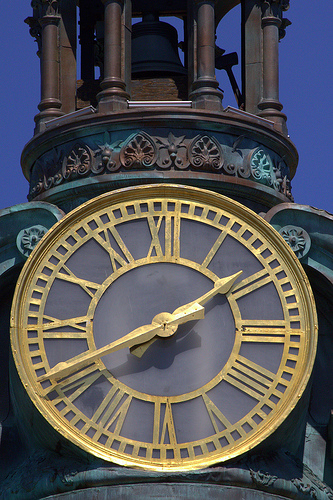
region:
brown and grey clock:
[10, 185, 317, 473]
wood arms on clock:
[42, 269, 241, 382]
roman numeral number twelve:
[146, 216, 180, 256]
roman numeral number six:
[152, 401, 175, 445]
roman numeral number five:
[201, 392, 230, 432]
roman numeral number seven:
[91, 385, 132, 435]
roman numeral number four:
[222, 355, 274, 399]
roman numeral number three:
[242, 316, 284, 345]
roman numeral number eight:
[49, 358, 99, 403]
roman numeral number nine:
[40, 314, 87, 339]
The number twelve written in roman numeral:
[141, 207, 186, 267]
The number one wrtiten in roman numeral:
[201, 227, 229, 268]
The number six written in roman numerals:
[150, 395, 178, 453]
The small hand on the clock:
[133, 270, 244, 317]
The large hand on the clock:
[29, 305, 204, 386]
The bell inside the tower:
[125, 14, 180, 85]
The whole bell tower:
[23, 2, 293, 195]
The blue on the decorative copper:
[44, 128, 289, 185]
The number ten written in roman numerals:
[55, 258, 102, 306]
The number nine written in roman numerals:
[37, 309, 95, 348]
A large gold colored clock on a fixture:
[8, 179, 323, 472]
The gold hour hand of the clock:
[168, 267, 247, 332]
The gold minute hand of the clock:
[36, 296, 205, 393]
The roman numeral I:
[200, 225, 228, 273]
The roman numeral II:
[219, 266, 274, 303]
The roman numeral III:
[233, 314, 289, 350]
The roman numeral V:
[196, 391, 236, 435]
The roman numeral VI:
[150, 395, 179, 450]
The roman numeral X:
[52, 262, 101, 303]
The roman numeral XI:
[92, 224, 136, 271]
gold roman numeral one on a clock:
[200, 230, 232, 269]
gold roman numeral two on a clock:
[225, 265, 272, 298]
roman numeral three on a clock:
[233, 319, 286, 343]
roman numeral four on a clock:
[221, 352, 275, 401]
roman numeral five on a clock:
[197, 390, 235, 431]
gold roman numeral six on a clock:
[151, 398, 180, 446]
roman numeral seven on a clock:
[90, 381, 133, 435]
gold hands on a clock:
[34, 269, 247, 383]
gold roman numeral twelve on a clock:
[144, 215, 184, 261]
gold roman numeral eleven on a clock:
[90, 225, 140, 272]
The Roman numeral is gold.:
[140, 208, 188, 263]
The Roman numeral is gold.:
[191, 223, 240, 271]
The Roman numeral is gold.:
[186, 386, 240, 440]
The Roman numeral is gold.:
[140, 390, 191, 461]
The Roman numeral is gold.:
[87, 380, 139, 440]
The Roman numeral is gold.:
[36, 307, 95, 346]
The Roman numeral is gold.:
[51, 255, 104, 298]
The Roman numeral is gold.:
[86, 216, 137, 274]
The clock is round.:
[9, 177, 321, 478]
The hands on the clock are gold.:
[6, 179, 321, 479]